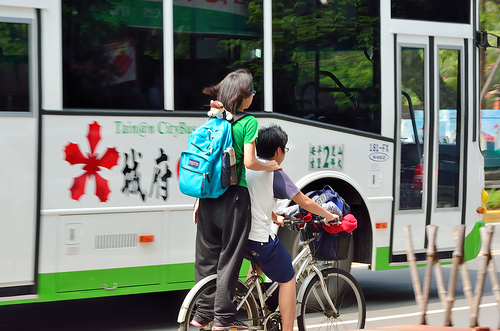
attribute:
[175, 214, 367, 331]
bicycle — white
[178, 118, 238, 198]
backpack — blue, light blue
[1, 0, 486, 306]
bus — big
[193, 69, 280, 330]
kid — standing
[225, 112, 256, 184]
shirt — green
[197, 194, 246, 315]
pants — black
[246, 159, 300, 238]
shirt — short sleeved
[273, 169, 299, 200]
sleeves — purple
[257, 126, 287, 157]
hair — black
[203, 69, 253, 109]
hair — brown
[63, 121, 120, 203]
symbol — red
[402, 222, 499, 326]
sticks — wooden